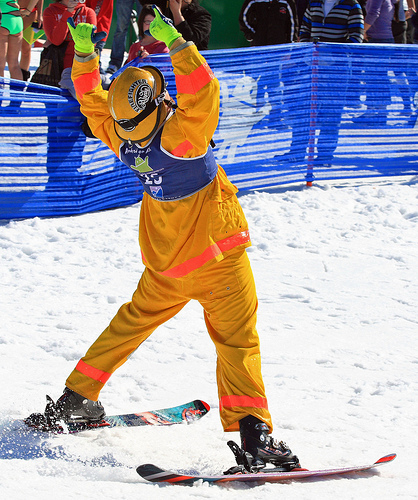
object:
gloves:
[138, 13, 181, 47]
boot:
[56, 387, 105, 425]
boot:
[237, 413, 298, 472]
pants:
[64, 250, 271, 430]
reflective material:
[218, 392, 268, 408]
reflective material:
[74, 357, 110, 382]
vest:
[120, 111, 217, 202]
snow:
[53, 447, 104, 465]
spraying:
[20, 439, 62, 462]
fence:
[221, 29, 395, 202]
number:
[137, 173, 162, 188]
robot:
[128, 150, 157, 174]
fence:
[3, 89, 85, 218]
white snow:
[302, 320, 343, 341]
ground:
[1, 117, 416, 498]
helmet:
[104, 66, 162, 143]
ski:
[136, 449, 397, 483]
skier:
[45, 0, 302, 471]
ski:
[24, 398, 211, 435]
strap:
[57, 389, 82, 407]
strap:
[242, 420, 264, 436]